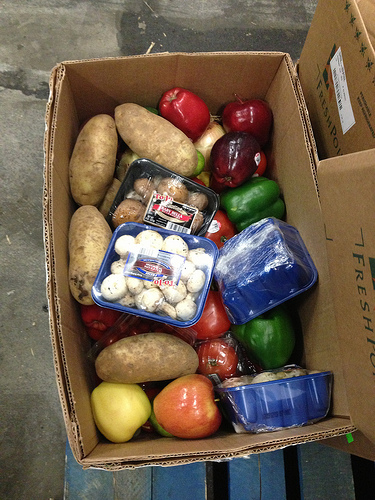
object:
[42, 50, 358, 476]
box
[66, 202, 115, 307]
vegetables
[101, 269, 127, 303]
mushrooms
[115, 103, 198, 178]
potato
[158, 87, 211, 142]
apple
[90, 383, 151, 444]
apple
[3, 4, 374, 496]
sidewalk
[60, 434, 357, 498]
table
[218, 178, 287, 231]
pepper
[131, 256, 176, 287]
label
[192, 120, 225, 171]
onion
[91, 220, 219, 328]
containers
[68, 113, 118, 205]
potatoes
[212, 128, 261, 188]
apple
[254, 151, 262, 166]
sticker